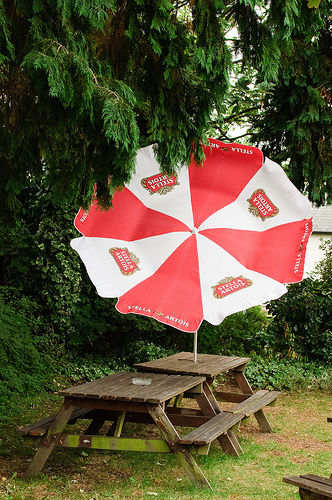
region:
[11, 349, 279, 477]
two weathered picnic tables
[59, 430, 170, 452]
a piece of wood with mold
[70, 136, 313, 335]
a red and white umbrella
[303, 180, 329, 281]
a white building with a gray roof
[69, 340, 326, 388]
green weeds growing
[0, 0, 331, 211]
a large green tree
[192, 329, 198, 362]
a silver metal post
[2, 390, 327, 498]
grassy flat land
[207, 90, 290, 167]
a gray sky seen through the tree branches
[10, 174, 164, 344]
plants growing up the hillside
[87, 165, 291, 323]
red and white umbrella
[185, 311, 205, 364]
white pole under umbrella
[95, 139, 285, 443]
umbrella in brown table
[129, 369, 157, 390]
ashtray on picnic table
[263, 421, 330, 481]
green and brown ground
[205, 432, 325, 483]
green and short grass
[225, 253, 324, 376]
green bushes behind table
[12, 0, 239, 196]
green and leafy trees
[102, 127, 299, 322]
beer manufacturer on umbrella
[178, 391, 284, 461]
wood seats on picnic table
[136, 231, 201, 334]
A red section of the umbrella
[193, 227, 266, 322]
A white section of the umbrella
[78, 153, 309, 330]
A red and white sectioned umbrella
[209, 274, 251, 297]
The stella artois logo on the umbrella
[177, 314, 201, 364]
The pole from the umbrella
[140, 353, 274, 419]
THe picnic table holding the umbrella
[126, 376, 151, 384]
The ashtray on the table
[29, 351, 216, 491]
The picnic table with the ash tray on it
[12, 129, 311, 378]
The trees behind the tables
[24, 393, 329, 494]
The grassy ground around the tables